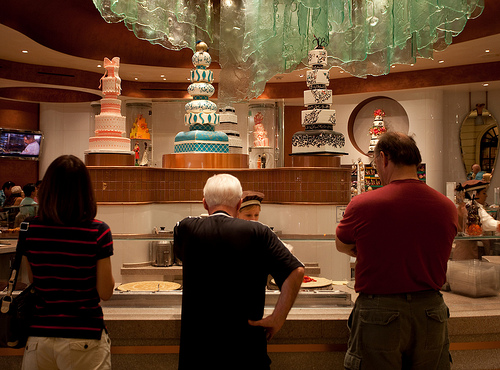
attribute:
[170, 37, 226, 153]
cake — white, iced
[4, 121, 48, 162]
t.v. — flat-screen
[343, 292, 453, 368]
pants — brown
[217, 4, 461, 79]
glass — green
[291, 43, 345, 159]
cake — white, iced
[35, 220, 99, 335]
shirt — black, red, striped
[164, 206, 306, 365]
t-shirt — black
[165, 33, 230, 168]
cake — blue, white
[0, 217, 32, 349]
purse — black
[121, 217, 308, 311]
shirt — black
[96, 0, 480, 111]
mirror — oblong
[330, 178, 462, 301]
shirt — maroon, short-sleeved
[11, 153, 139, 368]
woman — red, striped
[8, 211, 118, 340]
shirt — blue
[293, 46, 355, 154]
cake — multi-layered, white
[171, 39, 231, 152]
cake — blue, white, multi-layered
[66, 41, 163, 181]
cake — square, orange, multi-layered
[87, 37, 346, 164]
cakes — tall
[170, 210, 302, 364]
shirt — black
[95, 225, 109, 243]
stripe — red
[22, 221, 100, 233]
stripe — red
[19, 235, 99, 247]
stripe — red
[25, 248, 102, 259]
stripe — red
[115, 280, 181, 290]
platter — clean, empty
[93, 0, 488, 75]
decor — glass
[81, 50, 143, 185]
cake — large, orange, white, multi-tiered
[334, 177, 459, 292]
shirt — red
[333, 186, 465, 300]
shirt — burgundy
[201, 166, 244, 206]
hair — grey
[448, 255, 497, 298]
plate stack — white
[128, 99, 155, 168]
case — glass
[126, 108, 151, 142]
cake — small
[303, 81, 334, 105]
design — black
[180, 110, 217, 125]
purple decorations — iced